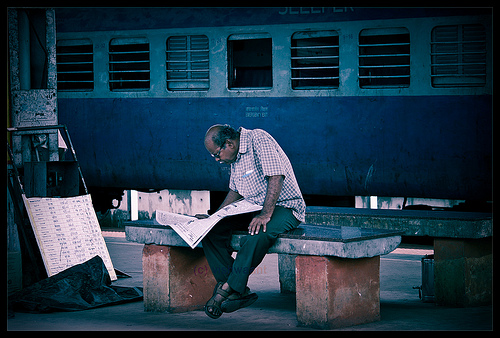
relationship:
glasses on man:
[210, 149, 222, 160] [203, 124, 307, 320]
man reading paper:
[203, 124, 307, 320] [156, 196, 265, 249]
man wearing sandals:
[203, 124, 307, 320] [204, 281, 258, 319]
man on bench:
[203, 124, 307, 320] [125, 224, 404, 328]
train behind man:
[56, 8, 497, 127] [203, 124, 307, 320]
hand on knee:
[245, 212, 272, 237] [248, 216, 278, 244]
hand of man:
[245, 212, 272, 237] [203, 124, 307, 320]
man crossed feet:
[203, 124, 307, 320] [204, 281, 258, 319]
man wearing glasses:
[203, 124, 307, 320] [210, 149, 222, 160]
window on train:
[290, 31, 341, 90] [56, 8, 497, 127]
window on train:
[110, 40, 148, 91] [56, 8, 497, 127]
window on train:
[355, 28, 408, 88] [56, 8, 497, 127]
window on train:
[431, 24, 486, 89] [56, 8, 497, 127]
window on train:
[166, 35, 209, 92] [56, 8, 497, 127]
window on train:
[56, 38, 93, 91] [56, 8, 497, 127]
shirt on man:
[229, 127, 307, 224] [203, 124, 307, 320]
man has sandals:
[203, 124, 307, 320] [204, 281, 258, 319]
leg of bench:
[294, 256, 380, 327] [125, 224, 404, 328]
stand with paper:
[5, 126, 117, 281] [25, 197, 117, 282]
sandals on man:
[204, 281, 258, 319] [203, 124, 307, 320]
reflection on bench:
[309, 226, 369, 241] [125, 224, 404, 328]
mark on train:
[243, 106, 270, 120] [56, 8, 497, 127]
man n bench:
[203, 124, 307, 320] [125, 224, 404, 328]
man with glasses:
[203, 124, 307, 320] [210, 149, 222, 160]